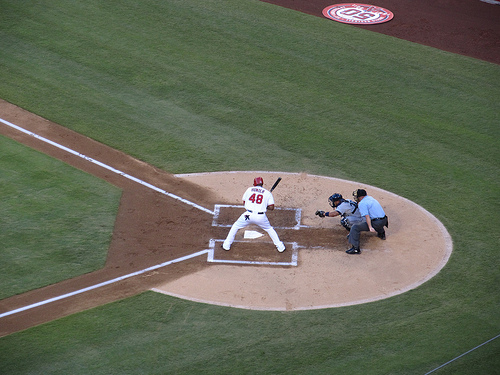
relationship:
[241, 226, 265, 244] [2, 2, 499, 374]
home plate of baseball field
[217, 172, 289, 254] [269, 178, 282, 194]
baseball player holding bat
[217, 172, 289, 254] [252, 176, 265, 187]
baseball player wearing helmet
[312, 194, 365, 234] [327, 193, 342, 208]
catcher wearing helmet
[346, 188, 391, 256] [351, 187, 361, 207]
umpire wearing mask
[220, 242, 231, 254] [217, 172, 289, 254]
shoe of baseball player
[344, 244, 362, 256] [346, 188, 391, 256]
shoe of umpire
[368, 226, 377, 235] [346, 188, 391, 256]
hand of umpire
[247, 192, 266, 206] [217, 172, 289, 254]
number of baseball player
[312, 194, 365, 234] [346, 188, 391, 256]
catcher in front of umpire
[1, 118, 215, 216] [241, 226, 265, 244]
line near home plate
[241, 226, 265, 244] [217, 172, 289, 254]
home plate beneath baseball player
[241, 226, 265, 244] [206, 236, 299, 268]
home plate near batter's box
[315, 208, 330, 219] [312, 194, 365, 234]
glove of catcher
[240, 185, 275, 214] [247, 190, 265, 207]
shirt with number 48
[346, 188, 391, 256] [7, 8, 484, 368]
umpire of a baseball game